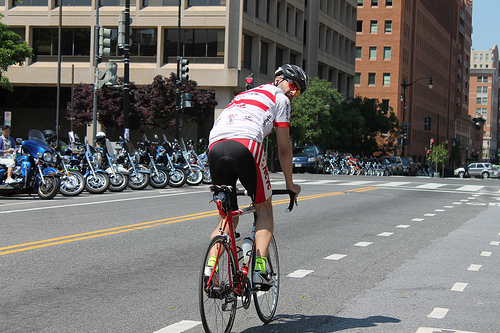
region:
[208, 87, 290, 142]
a red white and black shirt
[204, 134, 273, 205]
a red white and black pair of bike shorts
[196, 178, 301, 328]
a red white and black bike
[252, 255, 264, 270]
a bright yellow sock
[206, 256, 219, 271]
a bright yellow sock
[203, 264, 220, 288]
a black and white shoe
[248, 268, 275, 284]
a black and white shoe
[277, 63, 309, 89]
a black and white bike helmet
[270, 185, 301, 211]
a black bike handle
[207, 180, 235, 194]
a black bike seat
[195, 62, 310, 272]
man wearing red glasses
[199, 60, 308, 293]
man wearing a black bicycle helmet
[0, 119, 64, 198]
man sitting on a large, blue motorcycle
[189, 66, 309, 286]
man wearing a red, white, and black uniform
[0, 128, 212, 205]
many motorcycles parked on the side of the road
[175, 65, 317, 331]
man riding a bicycle on the road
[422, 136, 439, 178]
red stoplight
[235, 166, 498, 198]
white, striped crosswalk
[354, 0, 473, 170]
large, red bricked building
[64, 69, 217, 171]
two dark-leafed trees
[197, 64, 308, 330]
a man in red riding a bike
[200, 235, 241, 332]
rear wheel of a bicycle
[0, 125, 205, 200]
a row of motorcycles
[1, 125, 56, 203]
a person sitting on a motorcycle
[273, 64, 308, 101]
a man's head with a helmet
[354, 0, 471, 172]
a tall brick building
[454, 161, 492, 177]
a silver suv in the distance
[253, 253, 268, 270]
a man's neon green sock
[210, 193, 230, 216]
pack on the seat of a bicycle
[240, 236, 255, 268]
water bottle on a bike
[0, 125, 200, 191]
Multiple motorcycles in a row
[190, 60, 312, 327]
Byclist on the street looking behind him.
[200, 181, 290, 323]
Red bicycle with water bottle on the street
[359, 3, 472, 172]
The building is brick.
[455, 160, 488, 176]
The car is silver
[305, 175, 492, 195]
Crosswalk has zebra stripes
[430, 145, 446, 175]
A single tree along the street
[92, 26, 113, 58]
A stoplight on a post.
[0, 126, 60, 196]
A person sitting on a blue motorcycle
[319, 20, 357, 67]
Several windows on the side of the building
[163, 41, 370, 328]
a man on a bike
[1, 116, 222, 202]
a row of parked motorcycles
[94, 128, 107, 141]
a white motorcycle helmet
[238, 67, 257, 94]
a red traffic light over shoulder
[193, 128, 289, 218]
black biker shorts with red and white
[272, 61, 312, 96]
black helmet worn by bike rider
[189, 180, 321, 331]
a red bike with black handlebars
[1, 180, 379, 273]
double yellow line on road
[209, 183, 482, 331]
white dotted line on road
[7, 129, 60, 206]
front of a blue motorcycle